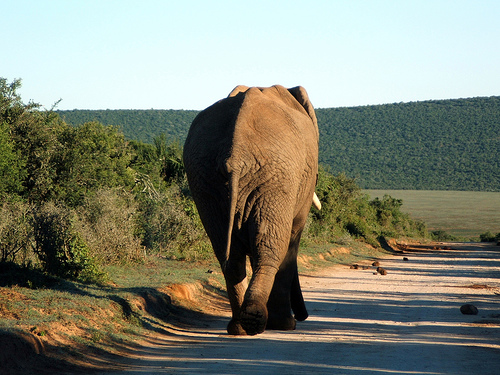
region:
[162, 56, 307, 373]
the elephant is walking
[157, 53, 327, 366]
the elephant is walking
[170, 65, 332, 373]
the elephant is walking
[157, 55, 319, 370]
the elephant is walking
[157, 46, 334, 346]
the elephant is walking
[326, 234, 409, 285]
dirt on the ground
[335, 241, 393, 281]
dirt on the ground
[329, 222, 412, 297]
dirt on the ground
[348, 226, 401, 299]
dirt on the ground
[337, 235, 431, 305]
dirt on the ground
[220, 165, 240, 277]
the tail of an elephant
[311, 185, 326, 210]
the tusk of an elephant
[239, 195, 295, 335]
the hind leg of an elephant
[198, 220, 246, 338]
the hind leg of an elephant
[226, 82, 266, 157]
the back of an elephant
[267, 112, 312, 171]
the skin of an elephant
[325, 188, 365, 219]
the leave of bushes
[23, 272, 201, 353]
the edge of a road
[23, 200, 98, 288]
a bush on the side of a road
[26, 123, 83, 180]
the leaves of some bushes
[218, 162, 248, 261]
tail of an elephant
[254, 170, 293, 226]
wrinkled skin of elephant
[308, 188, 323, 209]
part of the tusk of elephant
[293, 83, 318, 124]
the back of elephants ears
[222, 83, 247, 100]
the back of elephant ear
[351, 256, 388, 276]
rocks on the ground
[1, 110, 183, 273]
bushes line the path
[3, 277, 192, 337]
dirt and grass line the path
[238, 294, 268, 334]
bottom of elephant foot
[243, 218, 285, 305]
the leg of an elephant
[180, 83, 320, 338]
elephant walking down a path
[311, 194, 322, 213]
front right tusk of the elephant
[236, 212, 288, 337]
back right foot of the elephant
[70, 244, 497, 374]
dirt path in the elephant exhibit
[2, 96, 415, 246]
green shrubs on the side of the path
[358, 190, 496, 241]
large field in the distance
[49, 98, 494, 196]
hill with shrubs in the distance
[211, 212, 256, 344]
back left leg of the elephant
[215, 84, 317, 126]
ears of he elephant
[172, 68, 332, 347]
elephant walking down road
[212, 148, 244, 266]
short gray tail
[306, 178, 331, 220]
end of white tusk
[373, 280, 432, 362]
dirt road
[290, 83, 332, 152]
ear of the elephant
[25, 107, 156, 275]
green shrubbery side of road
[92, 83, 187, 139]
green forest in the distance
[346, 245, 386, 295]
brown elephant dung in road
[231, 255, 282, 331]
bent gray leg of elephant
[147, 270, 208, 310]
reddish dirt on the side of road